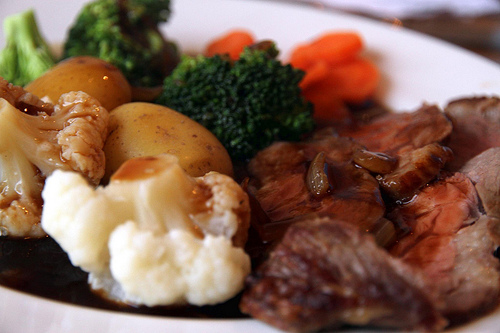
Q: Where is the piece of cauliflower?
A: On the plate.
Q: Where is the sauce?
A: On the plate.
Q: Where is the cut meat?
A: On the white plate.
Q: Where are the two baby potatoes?
A: Next to the cauliflower.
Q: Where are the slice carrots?
A: Next to the broccoli.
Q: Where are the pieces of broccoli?
A: On the plate.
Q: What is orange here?
A: Carrots.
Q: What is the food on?
A: A plate.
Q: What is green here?
A: Broccoli.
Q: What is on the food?
A: Gravy.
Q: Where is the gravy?
A: On the veggies.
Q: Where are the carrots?
A: On the plate.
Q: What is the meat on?
A: A plate.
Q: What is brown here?
A: Gravy.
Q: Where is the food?
A: On a plate.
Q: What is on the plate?
A: Food.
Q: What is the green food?
A: Brocolli.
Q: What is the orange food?
A: Carrots.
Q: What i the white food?
A: Cauliflour.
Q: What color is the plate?
A: White.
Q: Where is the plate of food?
A: On a table.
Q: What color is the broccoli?
A: Green.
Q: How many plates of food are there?
A: One.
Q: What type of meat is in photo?
A: Beef.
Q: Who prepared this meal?
A: A human.